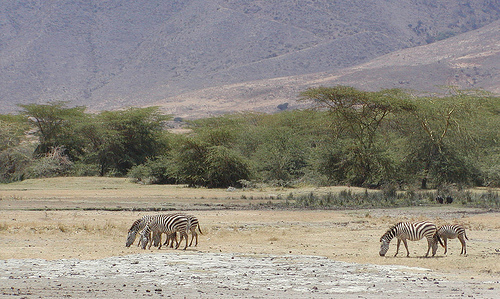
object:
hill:
[155, 17, 499, 110]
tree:
[293, 83, 418, 187]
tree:
[14, 99, 91, 156]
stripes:
[424, 231, 435, 236]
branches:
[335, 92, 367, 149]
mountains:
[0, 0, 500, 116]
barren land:
[0, 175, 499, 299]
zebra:
[432, 224, 469, 256]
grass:
[0, 173, 498, 274]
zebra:
[138, 214, 190, 251]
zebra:
[125, 214, 179, 248]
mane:
[379, 222, 403, 243]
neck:
[386, 226, 398, 241]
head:
[125, 231, 137, 248]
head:
[379, 239, 390, 256]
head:
[137, 231, 148, 250]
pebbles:
[311, 285, 319, 291]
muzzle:
[379, 252, 385, 256]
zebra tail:
[463, 228, 468, 240]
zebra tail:
[435, 226, 446, 248]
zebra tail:
[197, 220, 205, 236]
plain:
[0, 176, 497, 298]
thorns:
[105, 115, 159, 148]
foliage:
[2, 84, 497, 190]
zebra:
[152, 213, 203, 246]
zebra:
[378, 221, 444, 259]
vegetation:
[249, 185, 496, 211]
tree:
[93, 104, 174, 177]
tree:
[394, 128, 485, 190]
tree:
[162, 140, 250, 187]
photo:
[0, 0, 500, 298]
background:
[0, 0, 500, 114]